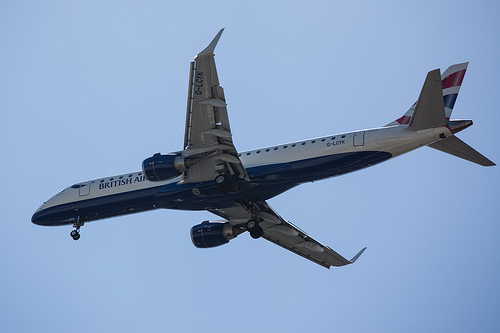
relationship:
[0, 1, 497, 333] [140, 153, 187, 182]
air has an engine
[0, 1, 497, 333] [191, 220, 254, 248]
air has an engine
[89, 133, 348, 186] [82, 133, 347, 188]
windows are in a row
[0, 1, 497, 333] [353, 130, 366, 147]
air has door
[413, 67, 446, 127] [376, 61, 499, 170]
wing on tail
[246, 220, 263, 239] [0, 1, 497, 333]
wheel on air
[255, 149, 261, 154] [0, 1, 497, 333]
window on air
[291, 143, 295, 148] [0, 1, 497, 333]
window on air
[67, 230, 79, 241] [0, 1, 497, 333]
wheel under front of air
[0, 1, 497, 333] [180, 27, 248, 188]
air has a wing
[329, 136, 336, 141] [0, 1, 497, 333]
window on air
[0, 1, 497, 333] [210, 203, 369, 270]
air has a wing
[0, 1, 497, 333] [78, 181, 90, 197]
air has door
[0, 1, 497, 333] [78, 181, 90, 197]
air has a door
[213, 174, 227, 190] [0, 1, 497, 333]
wheel under air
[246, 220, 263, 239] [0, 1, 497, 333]
wheel under air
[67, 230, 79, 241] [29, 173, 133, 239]
wheel in front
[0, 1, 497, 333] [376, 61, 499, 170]
air has a tail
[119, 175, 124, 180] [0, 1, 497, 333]
window on side of air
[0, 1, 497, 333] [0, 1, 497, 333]
air in air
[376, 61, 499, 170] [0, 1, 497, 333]
end of air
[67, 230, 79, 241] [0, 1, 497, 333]
wheel on front of air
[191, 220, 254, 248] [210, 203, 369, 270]
motor attatched to wing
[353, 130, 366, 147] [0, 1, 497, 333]
door on side of air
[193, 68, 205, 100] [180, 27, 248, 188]
number under wing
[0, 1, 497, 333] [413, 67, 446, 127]
air has a wing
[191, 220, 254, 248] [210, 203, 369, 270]
engine mounted under wing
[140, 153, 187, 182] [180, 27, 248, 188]
engine mounted under wing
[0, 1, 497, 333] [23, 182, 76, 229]
air has a nose